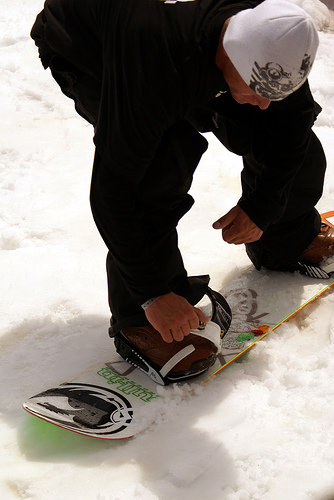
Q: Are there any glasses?
A: No, there are no glasses.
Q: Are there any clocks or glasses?
A: No, there are no glasses or clocks.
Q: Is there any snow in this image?
A: Yes, there is snow.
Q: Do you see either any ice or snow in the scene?
A: Yes, there is snow.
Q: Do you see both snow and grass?
A: No, there is snow but no grass.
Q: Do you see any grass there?
A: No, there is no grass.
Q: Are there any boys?
A: No, there are no boys.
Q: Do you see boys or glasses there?
A: No, there are no boys or glasses.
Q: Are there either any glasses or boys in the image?
A: No, there are no boys or glasses.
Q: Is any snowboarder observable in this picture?
A: Yes, there is a snowboarder.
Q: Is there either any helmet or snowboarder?
A: Yes, there is a snowboarder.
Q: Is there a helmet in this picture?
A: No, there are no helmets.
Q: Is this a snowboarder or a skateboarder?
A: This is a snowboarder.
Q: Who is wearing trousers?
A: The snowboarder is wearing trousers.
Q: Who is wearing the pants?
A: The snowboarder is wearing trousers.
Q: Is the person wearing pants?
A: Yes, the snowboarder is wearing pants.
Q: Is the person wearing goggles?
A: No, the snowboarder is wearing pants.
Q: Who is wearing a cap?
A: The snowboarder is wearing a cap.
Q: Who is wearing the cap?
A: The snowboarder is wearing a cap.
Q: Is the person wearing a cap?
A: Yes, the snowboarder is wearing a cap.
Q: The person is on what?
A: The snowboarder is on the snowboard.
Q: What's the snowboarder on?
A: The snowboarder is on the snowboard.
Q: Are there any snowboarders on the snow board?
A: Yes, there is a snowboarder on the snow board.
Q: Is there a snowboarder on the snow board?
A: Yes, there is a snowboarder on the snow board.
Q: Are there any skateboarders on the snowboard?
A: No, there is a snowboarder on the snowboard.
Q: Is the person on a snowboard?
A: Yes, the snowboarder is on a snowboard.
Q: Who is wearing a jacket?
A: The snowboarder is wearing a jacket.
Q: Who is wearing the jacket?
A: The snowboarder is wearing a jacket.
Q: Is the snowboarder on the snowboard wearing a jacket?
A: Yes, the snowboarder is wearing a jacket.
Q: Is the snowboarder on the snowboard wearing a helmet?
A: No, the snowboarder is wearing a jacket.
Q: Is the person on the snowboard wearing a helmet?
A: No, the snowboarder is wearing a jacket.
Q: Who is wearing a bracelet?
A: The snowboarder is wearing a bracelet.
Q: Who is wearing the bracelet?
A: The snowboarder is wearing a bracelet.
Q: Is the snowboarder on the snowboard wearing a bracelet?
A: Yes, the snowboarder is wearing a bracelet.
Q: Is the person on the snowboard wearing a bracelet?
A: Yes, the snowboarder is wearing a bracelet.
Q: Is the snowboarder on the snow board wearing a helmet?
A: No, the snowboarder is wearing a bracelet.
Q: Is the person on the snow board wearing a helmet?
A: No, the snowboarder is wearing a bracelet.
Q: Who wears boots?
A: The snowboarder wears boots.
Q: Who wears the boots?
A: The snowboarder wears boots.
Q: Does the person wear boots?
A: Yes, the snowboarder wears boots.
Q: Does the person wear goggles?
A: No, the snowboarder wears boots.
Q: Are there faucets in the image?
A: No, there are no faucets.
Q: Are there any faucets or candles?
A: No, there are no faucets or candles.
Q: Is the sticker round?
A: Yes, the sticker is round.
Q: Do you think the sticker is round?
A: Yes, the sticker is round.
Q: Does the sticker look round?
A: Yes, the sticker is round.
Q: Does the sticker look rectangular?
A: No, the sticker is round.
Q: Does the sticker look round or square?
A: The sticker is round.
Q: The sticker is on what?
A: The sticker is on the snow board.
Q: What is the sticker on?
A: The sticker is on the snow board.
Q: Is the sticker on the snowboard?
A: Yes, the sticker is on the snowboard.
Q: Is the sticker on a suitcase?
A: No, the sticker is on the snowboard.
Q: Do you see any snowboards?
A: Yes, there is a snowboard.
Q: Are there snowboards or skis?
A: Yes, there is a snowboard.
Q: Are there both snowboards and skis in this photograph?
A: No, there is a snowboard but no skis.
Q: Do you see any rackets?
A: No, there are no rackets.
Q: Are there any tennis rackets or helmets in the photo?
A: No, there are no tennis rackets or helmets.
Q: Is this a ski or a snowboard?
A: This is a snowboard.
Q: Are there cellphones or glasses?
A: No, there are no glasses or cellphones.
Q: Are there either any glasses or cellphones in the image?
A: No, there are no glasses or cellphones.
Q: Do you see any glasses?
A: No, there are no glasses.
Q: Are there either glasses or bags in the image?
A: No, there are no glasses or bags.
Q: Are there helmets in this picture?
A: No, there are no helmets.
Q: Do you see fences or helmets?
A: No, there are no helmets or fences.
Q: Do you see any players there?
A: No, there are no players.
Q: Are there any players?
A: No, there are no players.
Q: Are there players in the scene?
A: No, there are no players.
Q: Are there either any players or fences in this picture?
A: No, there are no players or fences.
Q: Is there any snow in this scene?
A: Yes, there is snow.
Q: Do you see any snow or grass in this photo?
A: Yes, there is snow.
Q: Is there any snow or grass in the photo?
A: Yes, there is snow.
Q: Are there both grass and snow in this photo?
A: No, there is snow but no grass.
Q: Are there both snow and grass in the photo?
A: No, there is snow but no grass.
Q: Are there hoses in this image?
A: No, there are no hoses.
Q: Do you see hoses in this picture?
A: No, there are no hoses.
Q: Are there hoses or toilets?
A: No, there are no hoses or toilets.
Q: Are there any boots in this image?
A: Yes, there are boots.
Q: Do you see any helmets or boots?
A: Yes, there are boots.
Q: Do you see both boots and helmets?
A: No, there are boots but no helmets.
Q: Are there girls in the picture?
A: No, there are no girls.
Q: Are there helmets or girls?
A: No, there are no girls or helmets.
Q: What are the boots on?
A: The boots are on the snow board.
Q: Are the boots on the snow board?
A: Yes, the boots are on the snow board.